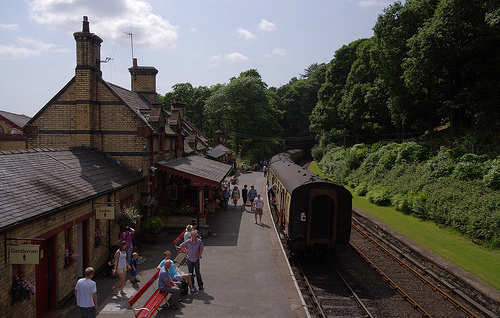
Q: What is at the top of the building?
A: Brown chimney.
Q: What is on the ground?
A: People standing and sitting around the bench.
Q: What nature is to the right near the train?
A: A line of leafy bushes next to the tracks.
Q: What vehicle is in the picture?
A: A train sitting on the track.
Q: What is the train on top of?
A: Tracks.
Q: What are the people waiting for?
A: The train.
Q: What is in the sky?
A: Clouds.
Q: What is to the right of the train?
A: Trees.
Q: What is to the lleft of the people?
A: A train station.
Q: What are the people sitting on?
A: A bench.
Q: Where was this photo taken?
A: At a train station.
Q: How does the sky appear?
A: Partly cloudy.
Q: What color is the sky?
A: Blue.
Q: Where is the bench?
A: Near the restrooms.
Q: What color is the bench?
A: Red.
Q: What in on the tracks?
A: A train.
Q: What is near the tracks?
A: Grass.